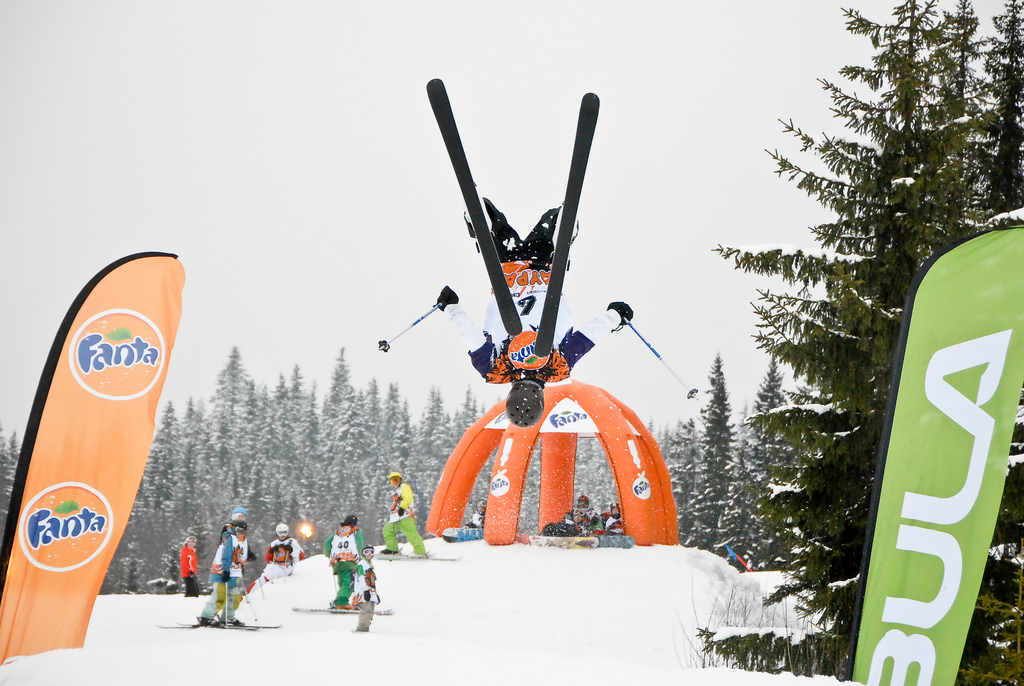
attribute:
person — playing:
[364, 466, 464, 571]